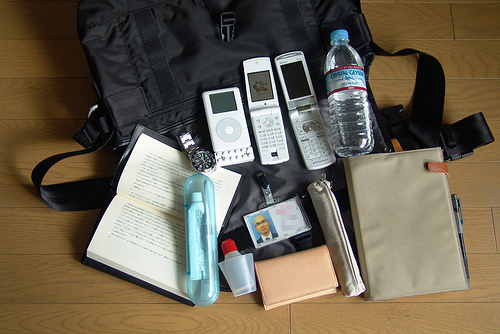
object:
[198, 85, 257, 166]
ipod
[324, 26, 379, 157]
bottle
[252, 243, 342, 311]
wallet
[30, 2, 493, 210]
bag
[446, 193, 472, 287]
pen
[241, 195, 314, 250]
id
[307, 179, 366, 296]
pouch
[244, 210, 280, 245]
man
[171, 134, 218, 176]
watch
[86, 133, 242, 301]
book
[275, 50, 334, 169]
cell phone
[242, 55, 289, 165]
cell phone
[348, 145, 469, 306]
diary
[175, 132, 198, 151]
strap